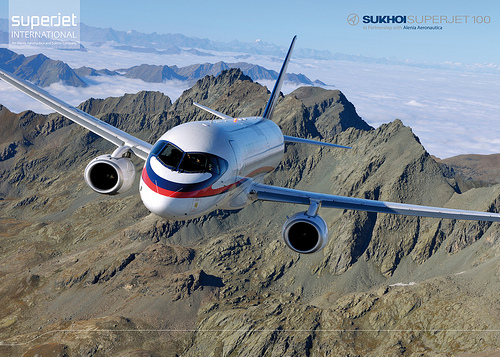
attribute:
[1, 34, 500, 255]
airplane — red, white, blue, flying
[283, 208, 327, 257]
engine — silver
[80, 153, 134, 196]
engine — silver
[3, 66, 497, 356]
mountain — large, brown, small, gray, tall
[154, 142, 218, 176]
window — large, black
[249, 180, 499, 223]
wing — small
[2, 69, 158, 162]
wing — small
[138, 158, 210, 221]
nose — red, white, blue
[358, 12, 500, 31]
lettering — blue, grey, white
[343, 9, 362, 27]
logo — white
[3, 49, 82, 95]
mountain — brown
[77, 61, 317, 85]
mountain — brown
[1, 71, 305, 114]
clouds — white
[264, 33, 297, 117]
tail — blue, gray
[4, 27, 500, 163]
clouds — gray, white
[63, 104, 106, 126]
logo — arrow, small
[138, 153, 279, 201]
stripes — red, blue